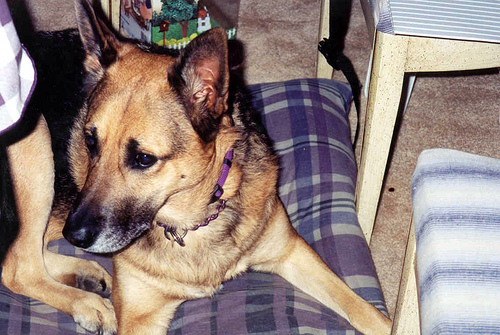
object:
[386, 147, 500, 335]
chair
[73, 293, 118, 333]
paw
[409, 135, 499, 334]
pillow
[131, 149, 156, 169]
eye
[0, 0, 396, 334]
dog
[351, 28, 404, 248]
leg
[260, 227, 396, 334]
leg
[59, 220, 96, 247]
nose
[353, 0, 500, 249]
table